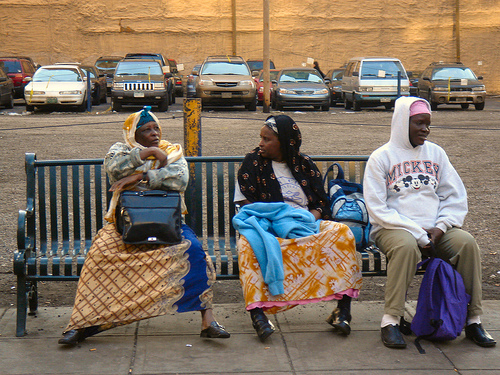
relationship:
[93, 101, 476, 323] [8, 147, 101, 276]
women on bench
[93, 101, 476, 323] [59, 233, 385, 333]
women are wearing skirts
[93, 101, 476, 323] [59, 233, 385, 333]
women wearing skirts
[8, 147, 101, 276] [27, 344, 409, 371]
bench at sidewalk